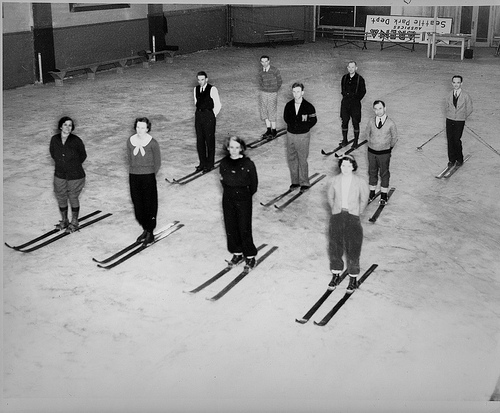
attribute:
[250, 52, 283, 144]
person — standing up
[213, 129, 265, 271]
person — standing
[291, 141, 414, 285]
person — standing up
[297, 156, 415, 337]
ski — black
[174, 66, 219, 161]
person — standing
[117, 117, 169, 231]
person — standing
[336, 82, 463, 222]
person — standing